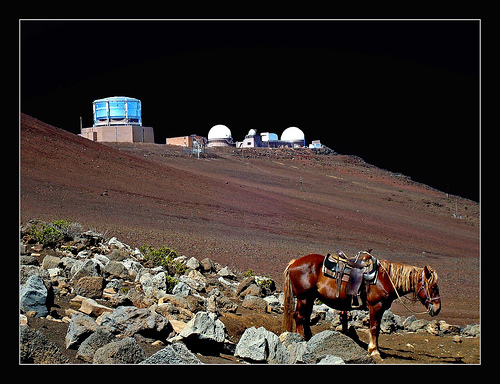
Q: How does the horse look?
A: It is brown with blonde hair.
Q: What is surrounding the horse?
A: A group of rocks.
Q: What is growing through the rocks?
A: Weeds are growing.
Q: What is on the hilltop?
A: Buildings are on the hilltop.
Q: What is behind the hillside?
A: A black sky.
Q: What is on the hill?
A: A horse.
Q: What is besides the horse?
A: Large rocks.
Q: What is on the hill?
A: Buildings are on the hill.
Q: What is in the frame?
A: A horse.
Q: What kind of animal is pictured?
A: 1.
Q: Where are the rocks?
A: Behind the horse.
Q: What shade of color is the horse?
A: Brown.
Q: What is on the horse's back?
A: Saddle.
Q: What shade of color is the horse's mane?
A: Light brown.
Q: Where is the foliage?
A: Growing between the rocks.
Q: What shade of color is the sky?
A: Black.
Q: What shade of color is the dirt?
A: Brown and reddish.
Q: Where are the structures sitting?
A: Top of the hill.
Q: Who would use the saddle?
A: Rider.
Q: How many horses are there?
A: One.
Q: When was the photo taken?
A: Night.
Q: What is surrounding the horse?
A: Large rocks.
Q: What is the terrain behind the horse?
A: Hillside.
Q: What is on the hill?
A: Buildings.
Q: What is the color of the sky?
A: Black.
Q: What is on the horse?
A: Saddle.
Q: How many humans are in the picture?
A: None.